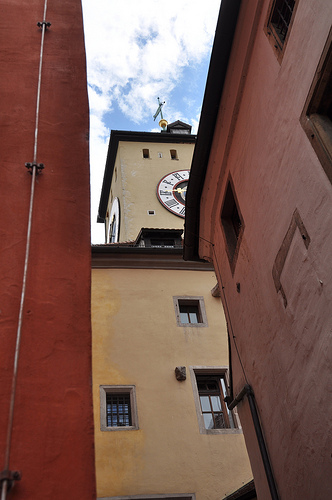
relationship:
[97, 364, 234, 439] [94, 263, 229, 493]
windows on a building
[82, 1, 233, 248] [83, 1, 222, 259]
cloud float through sky